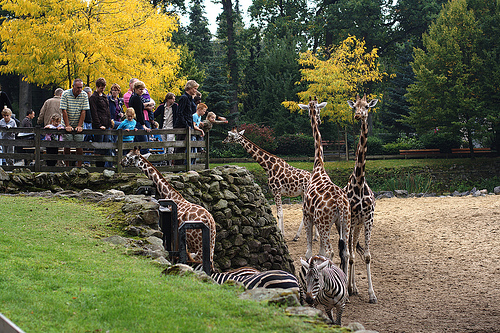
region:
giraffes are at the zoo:
[98, 111, 407, 208]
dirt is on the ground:
[414, 199, 496, 299]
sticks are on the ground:
[377, 196, 457, 306]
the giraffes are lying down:
[217, 260, 390, 314]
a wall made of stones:
[205, 187, 377, 281]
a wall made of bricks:
[73, 188, 220, 322]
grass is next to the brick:
[45, 208, 278, 325]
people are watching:
[17, 73, 352, 227]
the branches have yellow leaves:
[58, 22, 249, 135]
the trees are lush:
[206, 16, 440, 181]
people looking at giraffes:
[52, 58, 409, 298]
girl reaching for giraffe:
[198, 103, 310, 215]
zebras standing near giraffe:
[74, 109, 364, 326]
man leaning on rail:
[45, 73, 107, 164]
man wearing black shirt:
[170, 77, 203, 140]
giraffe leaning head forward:
[206, 115, 315, 230]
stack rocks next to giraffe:
[127, 136, 308, 309]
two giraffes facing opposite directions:
[283, 70, 400, 312]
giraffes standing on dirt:
[209, 87, 495, 327]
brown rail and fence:
[0, 106, 220, 187]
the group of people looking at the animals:
[0, 76, 214, 170]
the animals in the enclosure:
[120, 95, 379, 327]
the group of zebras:
[193, 255, 347, 327]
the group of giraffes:
[117, 90, 377, 302]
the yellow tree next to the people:
[0, 0, 187, 109]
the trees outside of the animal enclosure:
[0, 0, 498, 167]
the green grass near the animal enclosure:
[0, 194, 352, 329]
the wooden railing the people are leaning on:
[0, 124, 210, 173]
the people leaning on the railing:
[1, 75, 215, 168]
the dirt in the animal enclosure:
[264, 193, 497, 331]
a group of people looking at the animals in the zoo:
[1, 84, 222, 156]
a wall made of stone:
[106, 168, 290, 283]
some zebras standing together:
[219, 258, 351, 321]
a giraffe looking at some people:
[228, 120, 315, 235]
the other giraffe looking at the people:
[118, 146, 215, 265]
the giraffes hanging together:
[301, 90, 380, 296]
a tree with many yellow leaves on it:
[1, 2, 181, 98]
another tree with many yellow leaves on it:
[287, 42, 382, 130]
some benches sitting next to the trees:
[397, 146, 495, 158]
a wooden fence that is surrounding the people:
[1, 126, 209, 167]